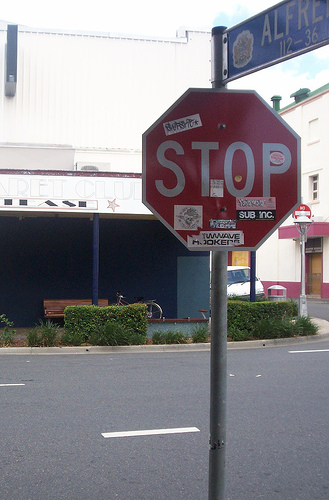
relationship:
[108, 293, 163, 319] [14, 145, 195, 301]
bicycle parked by building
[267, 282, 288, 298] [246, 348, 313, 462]
litter bin can by a road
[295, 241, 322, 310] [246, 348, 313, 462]
light pole by a road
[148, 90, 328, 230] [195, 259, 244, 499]
stop sign on pole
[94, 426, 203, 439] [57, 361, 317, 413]
line lines on road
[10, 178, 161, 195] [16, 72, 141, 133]
name of the club on building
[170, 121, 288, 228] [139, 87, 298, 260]
stickers on sign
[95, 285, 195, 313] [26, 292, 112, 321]
there is a bike next to the bench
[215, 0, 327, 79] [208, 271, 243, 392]
street sign on top of pole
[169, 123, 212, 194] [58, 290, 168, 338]
there is a streetlight next to bushes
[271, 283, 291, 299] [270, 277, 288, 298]
part of litter bin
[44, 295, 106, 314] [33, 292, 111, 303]
part of a bench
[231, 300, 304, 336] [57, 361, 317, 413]
hedge beside road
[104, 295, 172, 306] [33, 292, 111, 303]
bicycle sitting beside bench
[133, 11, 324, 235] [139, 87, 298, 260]
city street with sign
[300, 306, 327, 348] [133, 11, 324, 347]
curb separates sidewalk city street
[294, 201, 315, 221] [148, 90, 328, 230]
do not enter sign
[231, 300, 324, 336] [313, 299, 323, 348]
bushes behind street corner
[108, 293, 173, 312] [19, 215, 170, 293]
bicycle parked under building